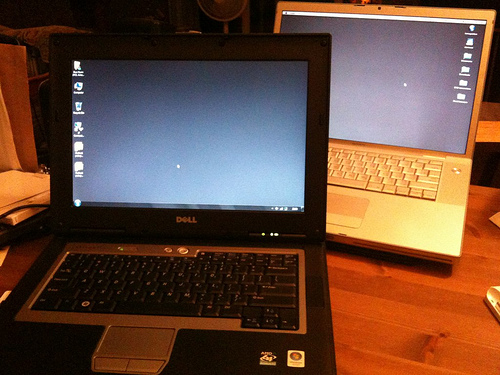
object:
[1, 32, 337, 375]
black computer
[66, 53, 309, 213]
screen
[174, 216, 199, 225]
logo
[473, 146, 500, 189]
ground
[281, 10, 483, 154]
screen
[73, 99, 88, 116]
recycle bin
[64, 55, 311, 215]
monitor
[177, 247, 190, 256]
button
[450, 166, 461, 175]
button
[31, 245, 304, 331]
keyboard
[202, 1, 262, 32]
fan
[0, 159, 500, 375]
desk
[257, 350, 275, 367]
sticker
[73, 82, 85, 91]
logo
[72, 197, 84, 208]
start button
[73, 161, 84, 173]
logo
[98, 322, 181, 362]
touchscreen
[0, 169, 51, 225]
stack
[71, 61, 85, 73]
icon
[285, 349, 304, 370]
sticker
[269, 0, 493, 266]
computer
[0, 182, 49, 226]
disk